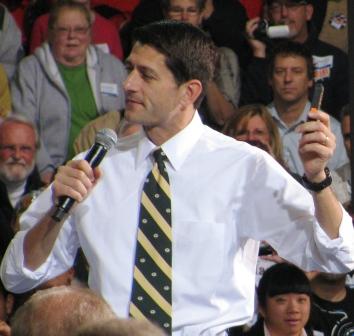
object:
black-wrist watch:
[302, 167, 333, 192]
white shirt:
[0, 109, 354, 336]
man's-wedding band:
[323, 136, 329, 146]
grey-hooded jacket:
[9, 43, 130, 180]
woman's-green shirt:
[56, 60, 99, 163]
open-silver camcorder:
[268, 25, 290, 40]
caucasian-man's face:
[122, 43, 164, 126]